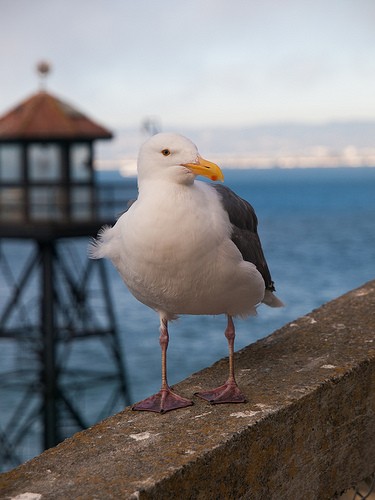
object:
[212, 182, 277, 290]
wing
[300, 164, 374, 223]
water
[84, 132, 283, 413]
bird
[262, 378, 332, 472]
wall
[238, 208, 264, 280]
feathers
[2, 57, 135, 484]
tower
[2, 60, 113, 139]
top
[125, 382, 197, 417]
foot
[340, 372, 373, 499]
wall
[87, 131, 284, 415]
seagull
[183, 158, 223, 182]
beak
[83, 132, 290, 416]
bird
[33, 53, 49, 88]
lightening rod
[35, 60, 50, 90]
rod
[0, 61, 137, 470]
lighthouse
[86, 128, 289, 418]
bird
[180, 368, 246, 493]
wall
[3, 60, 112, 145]
roof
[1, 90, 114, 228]
house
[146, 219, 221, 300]
breast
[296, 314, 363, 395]
wall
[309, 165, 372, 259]
ocean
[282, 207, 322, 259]
water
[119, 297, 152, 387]
water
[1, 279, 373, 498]
ledge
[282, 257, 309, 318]
water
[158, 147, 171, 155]
eye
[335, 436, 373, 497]
fence